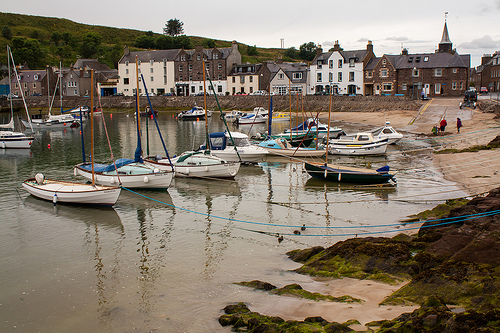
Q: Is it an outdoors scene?
A: Yes, it is outdoors.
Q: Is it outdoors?
A: Yes, it is outdoors.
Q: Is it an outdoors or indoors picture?
A: It is outdoors.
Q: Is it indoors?
A: No, it is outdoors.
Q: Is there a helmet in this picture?
A: No, there are no helmets.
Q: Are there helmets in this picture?
A: No, there are no helmets.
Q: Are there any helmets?
A: No, there are no helmets.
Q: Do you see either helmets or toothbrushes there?
A: No, there are no helmets or toothbrushes.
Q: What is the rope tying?
A: The rope is tying the boat.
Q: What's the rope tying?
A: The rope is tying the boat.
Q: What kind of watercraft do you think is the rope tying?
A: The rope is tying the boat.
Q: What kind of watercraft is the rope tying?
A: The rope is tying the boat.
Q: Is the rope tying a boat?
A: Yes, the rope is tying a boat.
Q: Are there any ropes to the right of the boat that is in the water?
A: Yes, there is a rope to the right of the boat.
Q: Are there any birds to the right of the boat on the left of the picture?
A: No, there is a rope to the right of the boat.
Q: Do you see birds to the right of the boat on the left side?
A: No, there is a rope to the right of the boat.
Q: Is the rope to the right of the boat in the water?
A: Yes, the rope is to the right of the boat.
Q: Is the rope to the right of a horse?
A: No, the rope is to the right of the boat.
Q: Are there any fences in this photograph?
A: No, there are no fences.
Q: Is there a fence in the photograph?
A: No, there are no fences.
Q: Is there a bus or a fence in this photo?
A: No, there are no fences or buses.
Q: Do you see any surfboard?
A: No, there are no surfboards.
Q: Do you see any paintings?
A: No, there are no paintings.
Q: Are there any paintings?
A: No, there are no paintings.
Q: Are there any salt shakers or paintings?
A: No, there are no paintings or salt shakers.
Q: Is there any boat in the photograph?
A: Yes, there is a boat.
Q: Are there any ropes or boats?
A: Yes, there is a boat.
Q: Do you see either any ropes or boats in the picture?
A: Yes, there is a boat.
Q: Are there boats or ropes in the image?
A: Yes, there is a boat.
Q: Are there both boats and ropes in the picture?
A: Yes, there are both a boat and a rope.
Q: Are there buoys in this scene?
A: No, there are no buoys.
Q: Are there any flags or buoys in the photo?
A: No, there are no buoys or flags.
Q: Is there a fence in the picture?
A: No, there are no fences.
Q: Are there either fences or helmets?
A: No, there are no fences or helmets.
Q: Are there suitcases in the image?
A: No, there are no suitcases.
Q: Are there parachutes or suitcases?
A: No, there are no suitcases or parachutes.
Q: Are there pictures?
A: No, there are no pictures.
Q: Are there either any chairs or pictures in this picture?
A: No, there are no pictures or chairs.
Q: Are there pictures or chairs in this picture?
A: No, there are no pictures or chairs.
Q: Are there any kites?
A: No, there are no kites.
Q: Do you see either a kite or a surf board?
A: No, there are no kites or surfboards.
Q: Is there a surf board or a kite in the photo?
A: No, there are no kites or surfboards.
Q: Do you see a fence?
A: No, there are no fences.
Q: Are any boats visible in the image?
A: Yes, there is a boat.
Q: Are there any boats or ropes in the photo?
A: Yes, there is a boat.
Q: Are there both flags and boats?
A: No, there is a boat but no flags.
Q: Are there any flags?
A: No, there are no flags.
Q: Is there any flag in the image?
A: No, there are no flags.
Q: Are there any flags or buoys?
A: No, there are no flags or buoys.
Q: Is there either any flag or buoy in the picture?
A: No, there are no flags or buoys.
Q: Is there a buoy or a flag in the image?
A: No, there are no flags or buoys.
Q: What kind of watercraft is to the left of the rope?
A: The watercraft is a boat.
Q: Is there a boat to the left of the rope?
A: Yes, there is a boat to the left of the rope.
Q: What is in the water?
A: The boat is in the water.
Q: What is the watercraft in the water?
A: The watercraft is a boat.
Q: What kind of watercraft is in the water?
A: The watercraft is a boat.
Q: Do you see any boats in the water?
A: Yes, there is a boat in the water.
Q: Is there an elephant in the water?
A: No, there is a boat in the water.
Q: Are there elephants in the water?
A: No, there is a boat in the water.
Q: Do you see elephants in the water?
A: No, there is a boat in the water.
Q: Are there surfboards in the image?
A: No, there are no surfboards.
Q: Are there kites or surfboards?
A: No, there are no surfboards or kites.